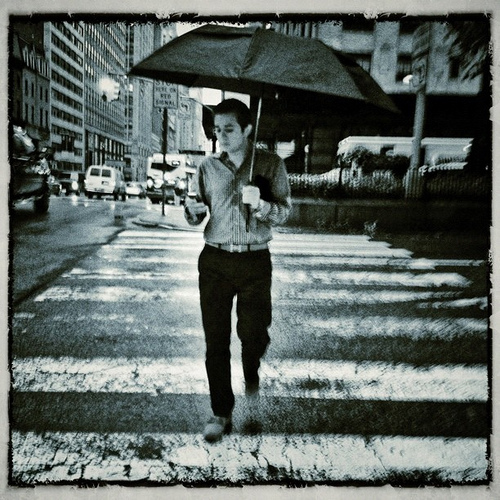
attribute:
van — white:
[83, 166, 121, 198]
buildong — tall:
[80, 17, 148, 194]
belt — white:
[203, 237, 270, 256]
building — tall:
[11, 19, 197, 201]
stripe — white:
[11, 355, 496, 399]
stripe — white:
[9, 430, 492, 483]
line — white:
[9, 427, 489, 482]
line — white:
[11, 354, 487, 404]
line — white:
[11, 310, 487, 340]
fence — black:
[288, 165, 493, 200]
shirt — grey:
[180, 149, 292, 246]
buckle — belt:
[224, 240, 246, 254]